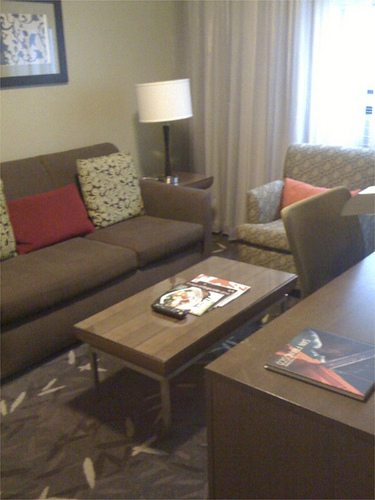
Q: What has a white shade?
A: Lamp.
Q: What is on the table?
A: Book.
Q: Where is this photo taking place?
A: In a living room.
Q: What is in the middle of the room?
A: Coffee table.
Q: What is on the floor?
A: A rug.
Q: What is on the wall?
A: A painting.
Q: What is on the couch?
A: Pillows.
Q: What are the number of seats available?
A: Five.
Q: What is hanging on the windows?
A: White curtains.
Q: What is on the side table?
A: Lamp.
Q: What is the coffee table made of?
A: Wood and metal.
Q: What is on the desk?
A: Book.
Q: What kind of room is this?
A: Living room.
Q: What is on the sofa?
A: Throw pillows.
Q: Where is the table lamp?
A: End table by the window.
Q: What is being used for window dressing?
A: Curtains.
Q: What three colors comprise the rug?
A: Beige, brown and white.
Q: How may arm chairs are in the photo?
A: One.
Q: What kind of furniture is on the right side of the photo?
A: Desk.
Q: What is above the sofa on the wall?
A: Framed painting.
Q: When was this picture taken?
A: Daytime.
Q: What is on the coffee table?
A: Remote control and magazines.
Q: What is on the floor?
A: Rug.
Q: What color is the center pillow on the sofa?
A: Red.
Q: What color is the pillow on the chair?
A: Orange.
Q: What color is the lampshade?
A: White.